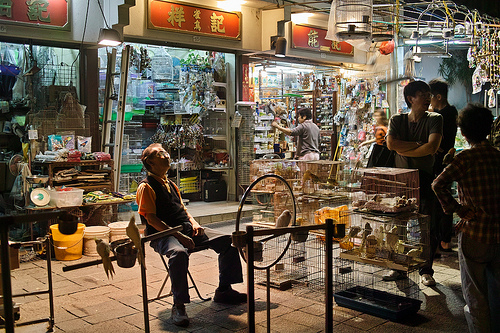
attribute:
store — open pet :
[66, 10, 428, 319]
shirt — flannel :
[436, 156, 497, 250]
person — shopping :
[385, 87, 445, 264]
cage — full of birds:
[338, 215, 422, 273]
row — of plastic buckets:
[50, 219, 150, 258]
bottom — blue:
[330, 290, 410, 314]